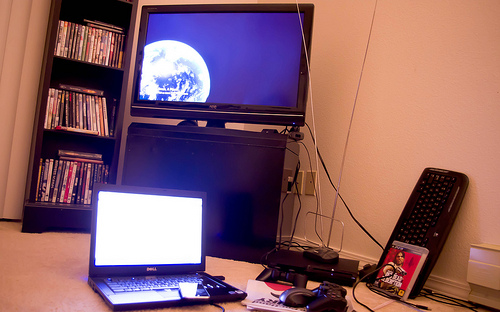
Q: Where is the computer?
A: On the floor.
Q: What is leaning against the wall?
A: A keyboard.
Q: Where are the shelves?
A: Against the wall.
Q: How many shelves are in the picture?
A: Three.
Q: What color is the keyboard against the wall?
A: Black.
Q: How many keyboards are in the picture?
A: Two.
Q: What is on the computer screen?
A: Nothing.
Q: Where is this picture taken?
A: In a living room.